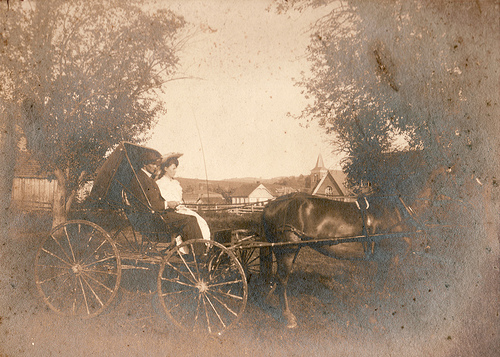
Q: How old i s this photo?
A: It is old.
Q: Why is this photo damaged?
A: It is old.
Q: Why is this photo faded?
A: It is old.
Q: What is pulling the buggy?
A: A horse.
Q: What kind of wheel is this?
A: A wagon wheel.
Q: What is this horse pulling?
A: A cart.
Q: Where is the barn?
A: It is in the background.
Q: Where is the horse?
A: It is in the foreground.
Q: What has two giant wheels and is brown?
A: A wagon in the foreground.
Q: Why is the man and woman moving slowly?
A: A horse is pulling the wagon.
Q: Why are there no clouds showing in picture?
A: Photo was taken in the daytime.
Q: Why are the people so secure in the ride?
A: Bottom of the wagon is made of wood.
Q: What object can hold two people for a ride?
A: A horse drawn buggy.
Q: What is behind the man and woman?
A: A large rear wheel.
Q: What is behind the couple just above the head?
A: Tree in the background.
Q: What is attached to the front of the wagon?
A: A horse standing.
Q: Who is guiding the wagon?
A: A man is driving the buggy.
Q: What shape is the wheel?
A: Round.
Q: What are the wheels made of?
A: Wood.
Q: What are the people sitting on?
A: Wagon.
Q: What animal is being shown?
A: Horse.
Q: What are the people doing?
A: Sitting.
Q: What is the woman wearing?
A: White dress.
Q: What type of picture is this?
A: Black and white.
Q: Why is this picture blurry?
A: It is faded.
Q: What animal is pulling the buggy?
A: A horse.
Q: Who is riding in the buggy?
A: A man and a woman.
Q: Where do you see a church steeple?
A: Behind the horse.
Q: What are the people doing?
A: Riding.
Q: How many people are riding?
A: 2.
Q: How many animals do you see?
A: 1.